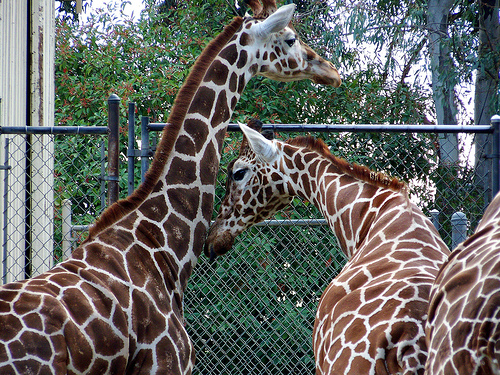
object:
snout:
[292, 30, 358, 98]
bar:
[138, 123, 499, 132]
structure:
[12, 24, 84, 284]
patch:
[291, 154, 325, 200]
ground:
[438, 127, 462, 173]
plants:
[44, 0, 497, 146]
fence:
[1, 89, 498, 374]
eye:
[229, 164, 249, 183]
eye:
[281, 34, 302, 48]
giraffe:
[2, 0, 341, 374]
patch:
[84, 241, 131, 284]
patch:
[127, 240, 174, 314]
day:
[2, 2, 499, 364]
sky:
[386, 25, 448, 85]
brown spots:
[92, 221, 184, 338]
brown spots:
[346, 268, 417, 350]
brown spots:
[450, 267, 499, 346]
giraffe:
[432, 180, 499, 373]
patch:
[313, 342, 328, 366]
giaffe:
[198, 112, 460, 370]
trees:
[62, 41, 132, 178]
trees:
[413, 7, 464, 196]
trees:
[474, 10, 497, 182]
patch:
[369, 205, 420, 245]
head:
[226, 1, 346, 91]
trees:
[51, 3, 434, 373]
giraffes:
[2, 4, 484, 363]